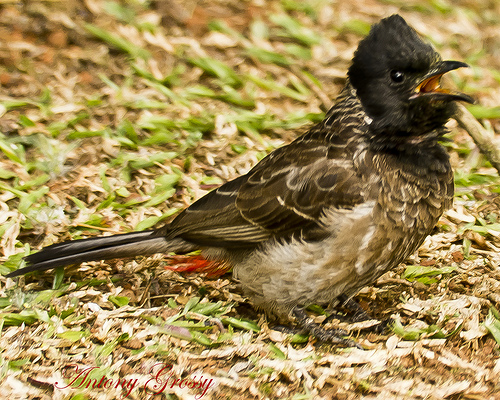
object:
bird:
[5, 13, 476, 348]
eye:
[388, 68, 407, 82]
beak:
[409, 60, 477, 106]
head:
[349, 13, 475, 139]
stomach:
[305, 212, 443, 317]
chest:
[377, 154, 456, 263]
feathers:
[164, 254, 231, 280]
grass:
[1, 2, 499, 398]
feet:
[290, 317, 366, 347]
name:
[53, 361, 215, 399]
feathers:
[258, 232, 366, 304]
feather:
[3, 234, 200, 279]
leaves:
[7, 37, 268, 400]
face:
[382, 48, 473, 122]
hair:
[348, 12, 438, 73]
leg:
[290, 302, 315, 328]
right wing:
[164, 142, 363, 252]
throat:
[370, 120, 450, 158]